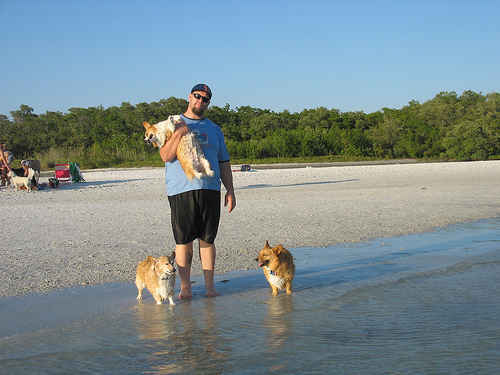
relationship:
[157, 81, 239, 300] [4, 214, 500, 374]
man standing in water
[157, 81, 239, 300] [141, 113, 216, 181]
man carrying dog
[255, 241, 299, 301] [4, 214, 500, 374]
dog standing in water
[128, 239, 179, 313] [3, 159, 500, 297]
dog standing on sand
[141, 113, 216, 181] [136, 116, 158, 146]
dog has head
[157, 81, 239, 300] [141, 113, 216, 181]
man has dog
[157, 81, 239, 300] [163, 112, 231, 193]
man wearing shirt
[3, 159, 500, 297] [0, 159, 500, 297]
sand of sand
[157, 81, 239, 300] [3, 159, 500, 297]
man on sand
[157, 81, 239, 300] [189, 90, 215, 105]
man wearing sunglasses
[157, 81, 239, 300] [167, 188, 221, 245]
man wearing shorts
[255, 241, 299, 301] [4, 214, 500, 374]
dog in water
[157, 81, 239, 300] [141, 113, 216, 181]
man holding dog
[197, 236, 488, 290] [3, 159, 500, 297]
shadow on sand